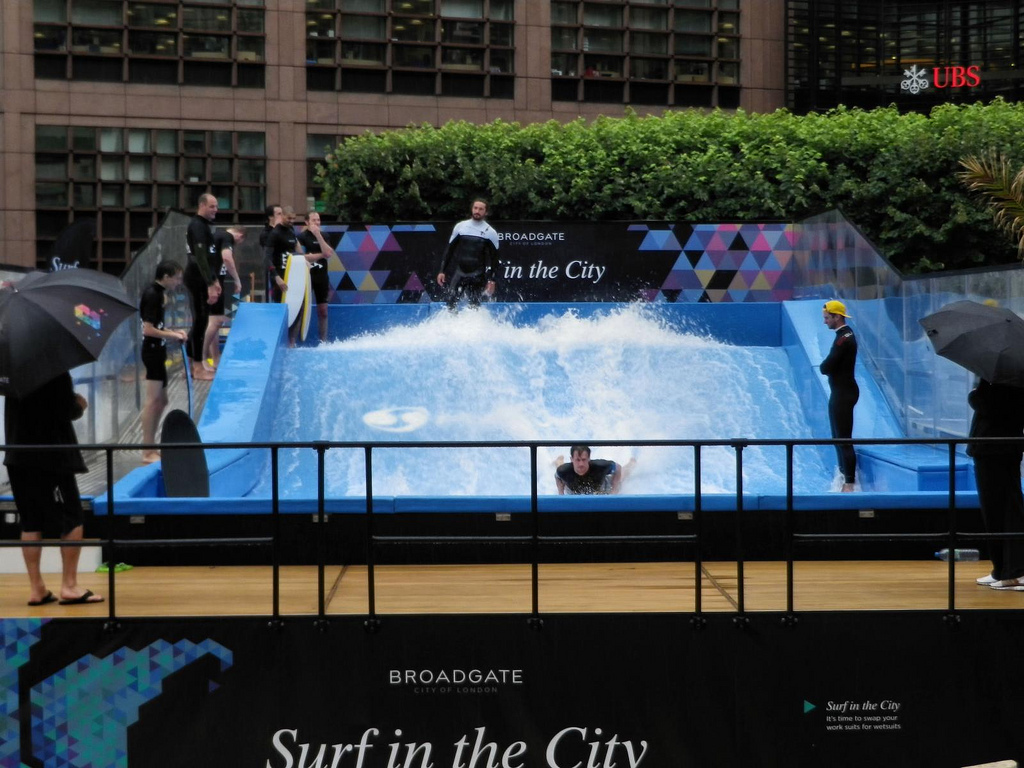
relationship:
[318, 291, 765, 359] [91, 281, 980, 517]
wavy water in enclosure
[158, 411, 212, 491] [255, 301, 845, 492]
skateboard in water